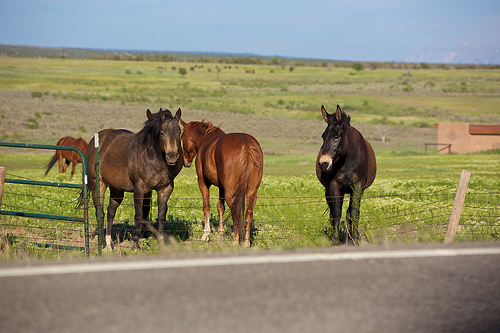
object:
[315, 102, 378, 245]
horse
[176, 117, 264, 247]
horse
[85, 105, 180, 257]
horse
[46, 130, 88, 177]
horse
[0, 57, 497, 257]
field